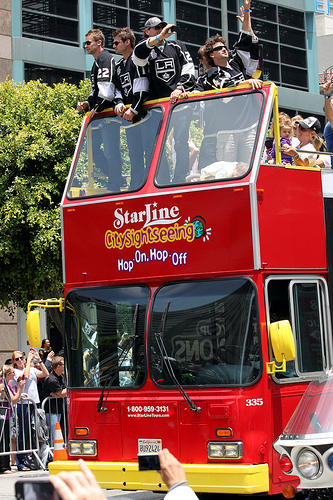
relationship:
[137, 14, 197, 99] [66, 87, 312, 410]
football player on bus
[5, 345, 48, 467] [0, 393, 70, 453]
man standing behind baracade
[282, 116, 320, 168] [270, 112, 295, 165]
woman carrying baby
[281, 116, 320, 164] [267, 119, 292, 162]
woman carrying a baby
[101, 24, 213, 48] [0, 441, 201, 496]
hand above a crowd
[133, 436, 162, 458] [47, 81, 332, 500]
license plate on a bus